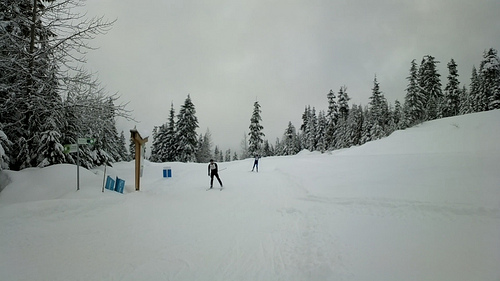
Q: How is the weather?
A: It is overcast.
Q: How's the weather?
A: It is overcast.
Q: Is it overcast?
A: Yes, it is overcast.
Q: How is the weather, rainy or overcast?
A: It is overcast.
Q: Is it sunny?
A: No, it is overcast.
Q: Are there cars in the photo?
A: No, there are no cars.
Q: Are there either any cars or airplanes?
A: No, there are no cars or airplanes.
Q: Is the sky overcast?
A: Yes, the sky is overcast.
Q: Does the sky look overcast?
A: Yes, the sky is overcast.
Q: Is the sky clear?
A: No, the sky is overcast.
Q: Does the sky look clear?
A: No, the sky is overcast.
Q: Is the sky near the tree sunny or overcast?
A: The sky is overcast.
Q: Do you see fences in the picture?
A: No, there are no fences.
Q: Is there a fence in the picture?
A: No, there are no fences.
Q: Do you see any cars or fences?
A: No, there are no fences or cars.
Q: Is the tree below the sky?
A: Yes, the tree is below the sky.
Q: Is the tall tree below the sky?
A: Yes, the tree is below the sky.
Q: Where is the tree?
A: The tree is in the snow.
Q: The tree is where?
A: The tree is on the snow.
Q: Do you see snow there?
A: Yes, there is snow.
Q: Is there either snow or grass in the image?
A: Yes, there is snow.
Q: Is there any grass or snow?
A: Yes, there is snow.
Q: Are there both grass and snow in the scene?
A: No, there is snow but no grass.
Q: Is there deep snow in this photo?
A: Yes, there is deep snow.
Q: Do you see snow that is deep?
A: Yes, there is snow that is deep.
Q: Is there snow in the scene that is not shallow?
A: Yes, there is deep snow.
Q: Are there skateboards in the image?
A: No, there are no skateboards.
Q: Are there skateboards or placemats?
A: No, there are no skateboards or placemats.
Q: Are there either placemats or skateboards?
A: No, there are no skateboards or placemats.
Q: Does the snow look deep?
A: Yes, the snow is deep.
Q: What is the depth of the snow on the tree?
A: The snow is deep.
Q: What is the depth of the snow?
A: The snow is deep.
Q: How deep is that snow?
A: The snow is deep.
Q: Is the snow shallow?
A: No, the snow is deep.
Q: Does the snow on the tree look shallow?
A: No, the snow is deep.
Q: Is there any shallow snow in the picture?
A: No, there is snow but it is deep.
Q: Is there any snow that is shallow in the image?
A: No, there is snow but it is deep.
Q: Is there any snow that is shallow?
A: No, there is snow but it is deep.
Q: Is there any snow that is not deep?
A: No, there is snow but it is deep.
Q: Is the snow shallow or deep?
A: The snow is deep.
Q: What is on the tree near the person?
A: The snow is on the tree.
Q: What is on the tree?
A: The snow is on the tree.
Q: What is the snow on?
A: The snow is on the tree.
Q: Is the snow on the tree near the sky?
A: Yes, the snow is on the tree.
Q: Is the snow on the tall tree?
A: Yes, the snow is on the tree.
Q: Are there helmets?
A: No, there are no helmets.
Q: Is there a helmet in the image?
A: No, there are no helmets.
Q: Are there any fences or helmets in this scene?
A: No, there are no helmets or fences.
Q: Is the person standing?
A: Yes, the person is standing.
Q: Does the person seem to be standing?
A: Yes, the person is standing.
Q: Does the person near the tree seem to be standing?
A: Yes, the person is standing.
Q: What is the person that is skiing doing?
A: The person is standing.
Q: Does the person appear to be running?
A: No, the person is standing.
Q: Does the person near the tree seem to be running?
A: No, the person is standing.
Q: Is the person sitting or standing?
A: The person is standing.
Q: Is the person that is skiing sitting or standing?
A: The person is standing.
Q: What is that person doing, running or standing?
A: The person is standing.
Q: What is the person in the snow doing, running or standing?
A: The person is standing.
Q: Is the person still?
A: Yes, the person is still.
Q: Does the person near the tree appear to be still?
A: Yes, the person is still.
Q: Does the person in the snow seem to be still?
A: Yes, the person is still.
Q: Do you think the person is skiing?
A: Yes, the person is skiing.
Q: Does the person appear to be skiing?
A: Yes, the person is skiing.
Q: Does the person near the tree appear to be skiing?
A: Yes, the person is skiing.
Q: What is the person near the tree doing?
A: The person is skiing.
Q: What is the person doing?
A: The person is skiing.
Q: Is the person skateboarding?
A: No, the person is skiing.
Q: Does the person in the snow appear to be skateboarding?
A: No, the person is skiing.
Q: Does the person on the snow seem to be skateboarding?
A: No, the person is skiing.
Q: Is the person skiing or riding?
A: The person is skiing.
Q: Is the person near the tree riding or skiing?
A: The person is skiing.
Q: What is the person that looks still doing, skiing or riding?
A: The person is skiing.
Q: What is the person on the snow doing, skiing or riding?
A: The person is skiing.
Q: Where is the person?
A: The person is in the snow.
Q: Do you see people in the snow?
A: Yes, there is a person in the snow.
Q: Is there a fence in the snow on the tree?
A: No, there is a person in the snow.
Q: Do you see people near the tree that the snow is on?
A: Yes, there is a person near the tree.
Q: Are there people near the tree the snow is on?
A: Yes, there is a person near the tree.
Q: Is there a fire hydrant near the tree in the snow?
A: No, there is a person near the tree.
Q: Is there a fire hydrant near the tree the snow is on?
A: No, there is a person near the tree.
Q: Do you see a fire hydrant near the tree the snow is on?
A: No, there is a person near the tree.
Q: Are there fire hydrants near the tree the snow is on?
A: No, there is a person near the tree.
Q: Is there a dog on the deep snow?
A: No, there is a person on the snow.